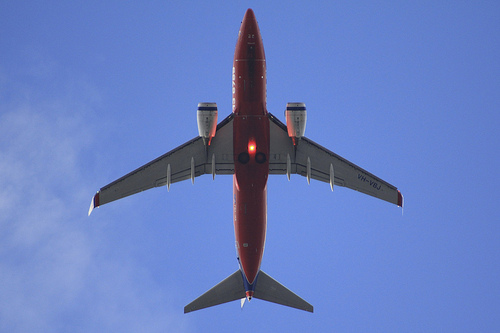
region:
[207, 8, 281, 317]
plane's body is red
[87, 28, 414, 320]
the plane in the sky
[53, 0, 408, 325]
Plane in the air.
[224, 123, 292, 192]
Light on the plane.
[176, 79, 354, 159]
Engines on the plane.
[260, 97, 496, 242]
Wing on the plane.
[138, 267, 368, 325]
Tail of the plane.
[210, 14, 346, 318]
Red body of the plane.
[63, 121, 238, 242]
Wing with an engine on it.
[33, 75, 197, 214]
White clouds in the sky.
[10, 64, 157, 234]
White clouds in the blue sky.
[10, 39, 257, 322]
Blue sky.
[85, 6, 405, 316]
Large red plane in sky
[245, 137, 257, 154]
Red light on plane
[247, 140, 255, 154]
Red light is lit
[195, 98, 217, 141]
Large jet engine on wing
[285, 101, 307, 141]
Large jet engine on wing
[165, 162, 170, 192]
Slat under large wing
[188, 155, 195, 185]
Slat under large wing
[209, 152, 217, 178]
Slat under large wing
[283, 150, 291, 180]
Slat under large wing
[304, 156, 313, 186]
Slat under large wing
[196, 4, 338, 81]
the nose of a plane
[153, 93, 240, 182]
the engine of a plane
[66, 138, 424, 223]
the wings of a plane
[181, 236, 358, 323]
the tail end on a plane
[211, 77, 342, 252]
the bottom of a plane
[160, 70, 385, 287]
a plane in the air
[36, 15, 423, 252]
a plane in the sky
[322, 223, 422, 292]
a clear blue sky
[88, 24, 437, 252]
a plane soaring in the sky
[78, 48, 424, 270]
a really big plane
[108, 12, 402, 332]
plane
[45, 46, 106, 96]
white clouds in blue sky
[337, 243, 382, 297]
white clouds in blue sky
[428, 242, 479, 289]
white clouds in blue sky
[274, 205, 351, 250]
white clouds in blue sky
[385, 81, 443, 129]
white clouds in blue sky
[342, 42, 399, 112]
white clouds in blue sky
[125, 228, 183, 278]
white clouds in blue sky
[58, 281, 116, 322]
white clouds in blue sky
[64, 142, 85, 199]
white clouds in blue sky